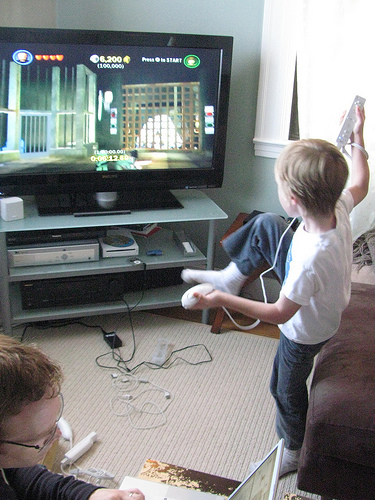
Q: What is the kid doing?
A: Playing video game.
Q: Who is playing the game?
A: Little boy.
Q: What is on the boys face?
A: Glasses.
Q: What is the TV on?
A: Stand.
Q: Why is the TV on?
A: Playing a game.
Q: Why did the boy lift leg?
A: To play game.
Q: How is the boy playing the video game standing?
A: On one foot.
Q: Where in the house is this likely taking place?
A: Living room.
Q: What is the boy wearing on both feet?
A: Socks.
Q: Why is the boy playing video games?
A: For fun.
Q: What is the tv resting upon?
A: Shelf.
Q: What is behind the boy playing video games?
A: Couch.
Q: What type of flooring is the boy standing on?
A: Carpet.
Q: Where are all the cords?
A: On the floor.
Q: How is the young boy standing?
A: With one foot in the air.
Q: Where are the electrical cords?
A: On the floor in front of the television.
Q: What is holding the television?
A: An entertainment center.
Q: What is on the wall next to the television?
A: A white wood framed window.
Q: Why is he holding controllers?
A: He's playing.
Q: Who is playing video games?
A: The boy.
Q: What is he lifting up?
A: His leg.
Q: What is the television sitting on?
A: A stand.